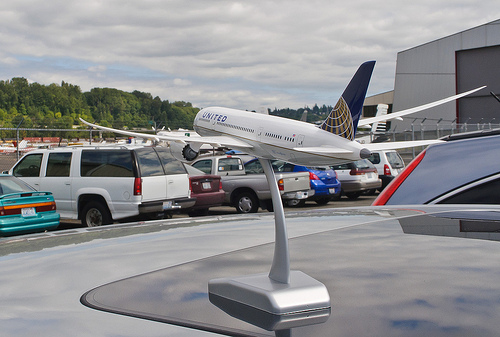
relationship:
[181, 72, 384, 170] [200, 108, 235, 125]
plane by united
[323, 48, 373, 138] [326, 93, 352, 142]
tail has globe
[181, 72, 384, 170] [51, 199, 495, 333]
plane on car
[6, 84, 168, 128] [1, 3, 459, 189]
trees are in background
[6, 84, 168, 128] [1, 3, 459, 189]
trees in background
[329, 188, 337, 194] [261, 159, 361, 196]
license plate on car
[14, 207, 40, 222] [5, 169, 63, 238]
license plate on car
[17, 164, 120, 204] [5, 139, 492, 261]
cars are in parking lot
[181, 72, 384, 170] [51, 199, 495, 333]
jet on a car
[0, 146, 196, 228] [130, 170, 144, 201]
cars has a light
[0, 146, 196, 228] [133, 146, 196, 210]
cars has two doors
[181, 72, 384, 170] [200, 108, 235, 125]
jet has words united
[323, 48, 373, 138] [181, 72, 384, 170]
tail of jet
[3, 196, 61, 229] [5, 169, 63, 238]
back of car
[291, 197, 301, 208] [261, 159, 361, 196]
tire on car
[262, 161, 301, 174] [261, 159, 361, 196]
side windows of car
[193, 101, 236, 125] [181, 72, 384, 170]
word on side of jet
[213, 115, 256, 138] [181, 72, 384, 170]
windows on side of jet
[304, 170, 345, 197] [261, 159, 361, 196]
back of car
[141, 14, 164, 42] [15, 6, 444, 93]
clouds in sky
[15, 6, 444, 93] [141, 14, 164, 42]
sky has clouds